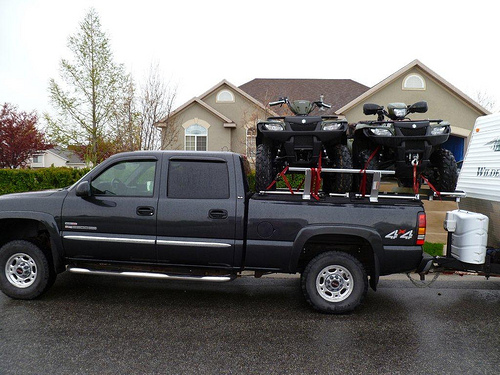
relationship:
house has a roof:
[148, 51, 495, 199] [238, 67, 373, 126]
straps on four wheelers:
[313, 163, 351, 186] [250, 92, 458, 193]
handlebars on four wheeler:
[259, 93, 346, 118] [7, 149, 378, 324]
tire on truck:
[301, 247, 375, 314] [0, 151, 425, 316]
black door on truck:
[62, 156, 159, 272] [0, 151, 425, 316]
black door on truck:
[158, 151, 238, 282] [0, 151, 425, 316]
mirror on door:
[71, 173, 96, 198] [63, 199, 166, 266]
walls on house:
[185, 71, 485, 197] [153, 53, 495, 175]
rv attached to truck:
[441, 110, 499, 277] [0, 151, 425, 316]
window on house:
[164, 109, 230, 165] [156, 39, 469, 284]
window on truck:
[166, 158, 231, 201] [0, 151, 425, 316]